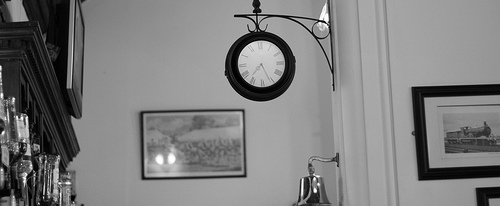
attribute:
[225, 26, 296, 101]
clock — hanging, circular, inside, black, white, round, metal, 7:25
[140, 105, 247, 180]
picture — black, white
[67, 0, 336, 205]
wall — blank, white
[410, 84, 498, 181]
picture — black, white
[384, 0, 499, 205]
wall — white, blank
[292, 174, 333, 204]
bell — silver, metal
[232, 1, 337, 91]
rod — metal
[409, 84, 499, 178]
frame — black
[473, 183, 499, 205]
frame — black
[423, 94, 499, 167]
matte — white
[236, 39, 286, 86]
face — white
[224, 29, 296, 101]
clock frame — black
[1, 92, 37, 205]
wine bottles — upside down